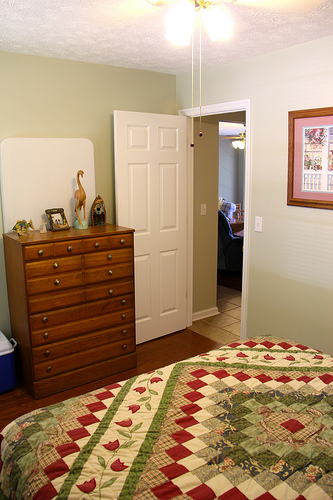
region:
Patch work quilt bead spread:
[86, 398, 325, 486]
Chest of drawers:
[5, 220, 138, 378]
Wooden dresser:
[9, 235, 146, 385]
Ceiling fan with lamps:
[143, 0, 258, 164]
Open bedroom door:
[109, 93, 307, 375]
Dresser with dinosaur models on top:
[9, 157, 137, 361]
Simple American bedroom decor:
[17, 84, 302, 411]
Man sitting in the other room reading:
[125, 91, 302, 390]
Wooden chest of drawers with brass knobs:
[9, 161, 146, 398]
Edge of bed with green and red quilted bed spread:
[23, 327, 315, 480]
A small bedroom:
[1, 6, 331, 498]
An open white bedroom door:
[119, 111, 191, 346]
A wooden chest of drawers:
[17, 226, 137, 384]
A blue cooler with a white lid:
[0, 328, 18, 398]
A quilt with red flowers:
[23, 352, 329, 498]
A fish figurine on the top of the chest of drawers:
[9, 217, 36, 233]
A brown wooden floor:
[138, 336, 204, 363]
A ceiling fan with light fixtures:
[225, 132, 248, 150]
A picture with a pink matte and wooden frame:
[285, 108, 331, 205]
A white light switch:
[254, 216, 263, 234]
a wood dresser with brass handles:
[9, 241, 159, 379]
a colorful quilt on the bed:
[20, 345, 320, 495]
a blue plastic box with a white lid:
[0, 324, 23, 394]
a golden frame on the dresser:
[46, 203, 73, 232]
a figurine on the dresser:
[68, 168, 93, 230]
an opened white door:
[113, 113, 226, 329]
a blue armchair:
[220, 210, 244, 282]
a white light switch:
[200, 199, 209, 221]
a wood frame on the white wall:
[278, 106, 331, 236]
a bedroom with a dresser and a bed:
[3, 115, 323, 497]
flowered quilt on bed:
[72, 336, 299, 499]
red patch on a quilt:
[189, 363, 211, 382]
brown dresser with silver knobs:
[14, 230, 129, 392]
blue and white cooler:
[0, 329, 25, 387]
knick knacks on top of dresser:
[11, 168, 113, 250]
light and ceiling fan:
[211, 123, 252, 161]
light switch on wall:
[228, 215, 287, 239]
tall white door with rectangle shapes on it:
[133, 128, 189, 337]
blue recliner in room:
[210, 204, 244, 301]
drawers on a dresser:
[29, 295, 136, 383]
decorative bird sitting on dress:
[64, 166, 93, 227]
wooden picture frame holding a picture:
[44, 200, 72, 233]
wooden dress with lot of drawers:
[12, 229, 162, 403]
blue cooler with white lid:
[1, 318, 30, 396]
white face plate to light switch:
[196, 194, 212, 226]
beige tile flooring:
[206, 299, 248, 349]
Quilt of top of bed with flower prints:
[7, 361, 329, 498]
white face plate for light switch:
[247, 206, 280, 249]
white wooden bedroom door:
[107, 101, 242, 361]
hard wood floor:
[143, 322, 229, 363]